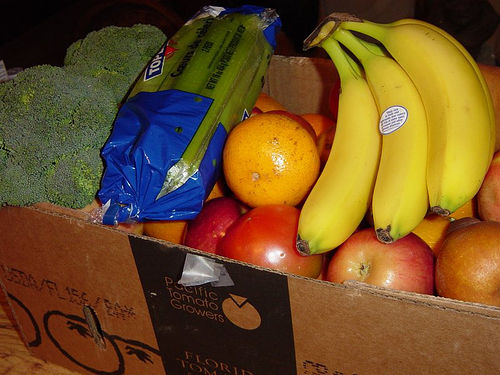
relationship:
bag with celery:
[98, 180, 161, 214] [161, 26, 227, 165]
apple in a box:
[195, 202, 225, 249] [280, 57, 325, 100]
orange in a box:
[233, 116, 309, 185] [280, 57, 325, 100]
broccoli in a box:
[32, 77, 88, 130] [280, 57, 325, 100]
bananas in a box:
[358, 58, 431, 154] [280, 57, 325, 100]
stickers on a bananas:
[384, 102, 406, 133] [358, 58, 431, 154]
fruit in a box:
[240, 89, 467, 294] [280, 57, 325, 100]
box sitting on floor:
[280, 57, 325, 100] [11, 352, 51, 374]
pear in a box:
[441, 221, 499, 303] [280, 57, 325, 100]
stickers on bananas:
[384, 102, 406, 133] [358, 58, 431, 154]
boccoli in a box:
[33, 78, 98, 164] [280, 57, 325, 100]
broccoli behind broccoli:
[32, 77, 88, 130] [97, 31, 149, 62]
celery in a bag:
[161, 26, 227, 165] [98, 180, 161, 214]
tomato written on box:
[165, 286, 219, 310] [280, 57, 325, 100]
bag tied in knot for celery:
[98, 180, 161, 214] [161, 26, 227, 165]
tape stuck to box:
[177, 253, 235, 292] [280, 57, 325, 100]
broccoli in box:
[32, 77, 88, 130] [280, 57, 325, 100]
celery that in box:
[161, 26, 227, 165] [280, 57, 325, 100]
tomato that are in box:
[220, 206, 318, 279] [280, 57, 325, 100]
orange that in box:
[233, 116, 309, 185] [280, 57, 325, 100]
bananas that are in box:
[358, 58, 431, 154] [280, 57, 325, 100]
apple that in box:
[195, 202, 225, 249] [280, 57, 325, 100]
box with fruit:
[280, 57, 325, 100] [240, 89, 467, 294]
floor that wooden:
[11, 352, 51, 374] [4, 325, 14, 372]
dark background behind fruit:
[30, 10, 76, 31] [240, 89, 467, 294]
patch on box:
[130, 264, 191, 351] [280, 57, 325, 100]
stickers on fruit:
[384, 102, 406, 133] [240, 89, 467, 294]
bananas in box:
[358, 58, 431, 154] [280, 57, 325, 100]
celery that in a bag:
[161, 26, 227, 165] [98, 180, 161, 214]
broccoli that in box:
[32, 77, 88, 130] [280, 57, 325, 100]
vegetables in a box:
[15, 49, 223, 192] [280, 57, 325, 100]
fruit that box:
[240, 89, 467, 294] [280, 57, 325, 100]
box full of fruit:
[280, 57, 325, 100] [240, 89, 467, 294]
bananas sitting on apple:
[358, 58, 431, 154] [195, 202, 225, 249]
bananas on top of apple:
[358, 58, 431, 154] [195, 202, 225, 249]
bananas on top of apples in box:
[358, 58, 431, 154] [280, 57, 325, 100]